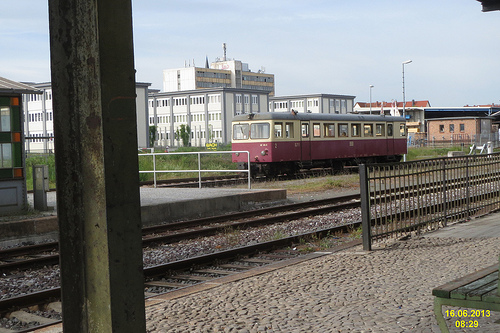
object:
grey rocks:
[146, 237, 500, 332]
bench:
[431, 263, 500, 332]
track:
[0, 169, 500, 333]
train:
[138, 175, 267, 188]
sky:
[147, 0, 493, 40]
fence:
[358, 151, 500, 251]